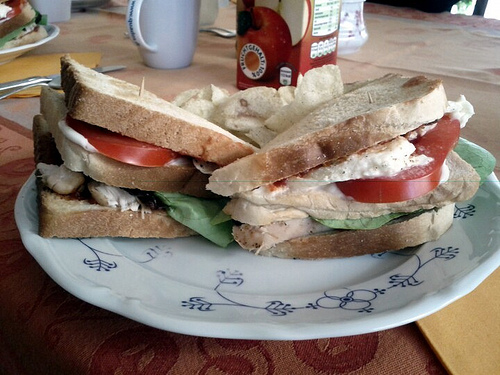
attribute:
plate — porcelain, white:
[10, 123, 497, 340]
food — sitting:
[32, 54, 471, 253]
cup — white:
[112, 224, 490, 308]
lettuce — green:
[154, 192, 222, 258]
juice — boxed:
[237, 0, 338, 89]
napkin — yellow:
[0, 47, 114, 107]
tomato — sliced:
[341, 120, 464, 212]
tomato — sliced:
[65, 113, 183, 168]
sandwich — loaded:
[225, 64, 476, 258]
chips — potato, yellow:
[210, 86, 297, 133]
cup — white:
[124, 4, 204, 69]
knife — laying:
[1, 60, 129, 106]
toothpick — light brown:
[138, 73, 146, 96]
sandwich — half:
[31, 48, 243, 243]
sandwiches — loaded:
[48, 42, 462, 252]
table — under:
[1, 1, 498, 373]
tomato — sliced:
[350, 144, 445, 204]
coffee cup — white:
[125, 0, 201, 71]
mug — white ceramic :
[114, 4, 215, 84]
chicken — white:
[244, 173, 482, 243]